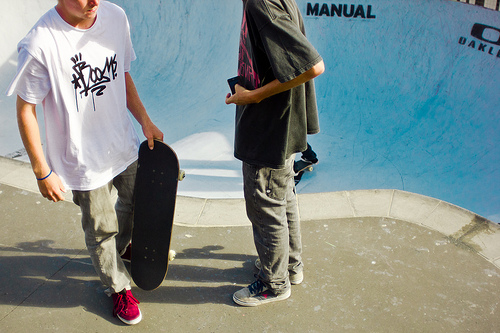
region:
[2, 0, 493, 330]
Two young men in a skate park.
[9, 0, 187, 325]
One man holding a skateboard.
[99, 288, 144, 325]
The right red sneaker.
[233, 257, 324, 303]
The grey sneakers with a red design.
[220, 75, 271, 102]
The skateboarder holding something in his hand.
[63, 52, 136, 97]
The writing on the man's tee shirt.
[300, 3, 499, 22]
The words written on the skate park wall.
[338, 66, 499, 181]
The blue skate park walls.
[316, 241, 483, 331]
The cement ground surface.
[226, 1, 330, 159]
The skateboarder's black shirt.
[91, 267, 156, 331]
shoe is red and clean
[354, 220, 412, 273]
white spots on the ground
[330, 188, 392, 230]
white wall with lines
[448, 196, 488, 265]
black spot on wall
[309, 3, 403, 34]
black words on wall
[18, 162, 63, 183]
blue band on man's wrist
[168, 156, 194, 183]
wheels on skating board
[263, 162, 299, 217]
gray pocket on pants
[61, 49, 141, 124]
black symbol on tee shirt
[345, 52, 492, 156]
blue wall with faint lines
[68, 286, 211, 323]
red and white sneakers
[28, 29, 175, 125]
T-shirt with graffiti logo.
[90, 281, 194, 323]
Red shoe with white sole.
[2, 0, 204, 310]
Young man holding a skateboard.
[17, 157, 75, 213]
Man wearing rubber band on wrist.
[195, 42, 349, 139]
Young man holding a cell phone.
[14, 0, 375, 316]
Two young men at a skate park.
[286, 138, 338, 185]
Person riding a skateboard.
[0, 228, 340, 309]
Shadows of two young men.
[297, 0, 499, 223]
Blue wall of sloped pit in skate park.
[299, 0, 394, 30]
Advertisement for skateboard gear.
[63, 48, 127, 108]
The black design on the white t-shirt.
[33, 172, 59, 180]
The blue bracelet on the skater's wrist.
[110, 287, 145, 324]
The pink sneaker of the skater.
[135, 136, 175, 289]
The black skateboard the skateboard is holding.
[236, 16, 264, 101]
The pink design on the black t-shirt.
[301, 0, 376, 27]
The word on the ramp starting with the letter M.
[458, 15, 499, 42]
The Oakley emblem.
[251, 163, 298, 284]
The gray pants the skater in the black shirt is wearing.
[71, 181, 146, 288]
The gray pants the skater in the white shirt is wearing.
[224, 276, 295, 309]
The gray sneaker the skater in the black shirt is wearing.